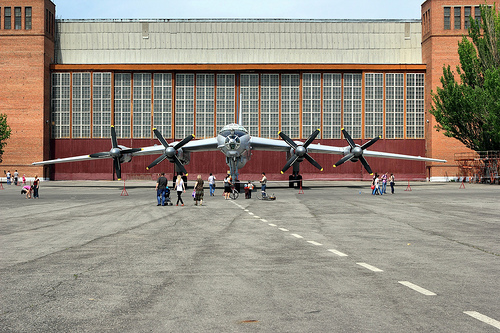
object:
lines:
[219, 194, 498, 332]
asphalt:
[0, 182, 499, 331]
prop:
[332, 127, 381, 176]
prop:
[145, 127, 196, 176]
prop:
[87, 125, 141, 181]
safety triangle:
[403, 180, 412, 191]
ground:
[2, 176, 500, 333]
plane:
[25, 123, 449, 196]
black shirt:
[157, 177, 167, 189]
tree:
[431, 0, 500, 179]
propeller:
[275, 129, 324, 175]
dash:
[0, 177, 500, 298]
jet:
[22, 121, 448, 193]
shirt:
[23, 185, 32, 192]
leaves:
[426, 3, 500, 157]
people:
[18, 169, 415, 207]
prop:
[28, 121, 451, 194]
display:
[31, 123, 448, 193]